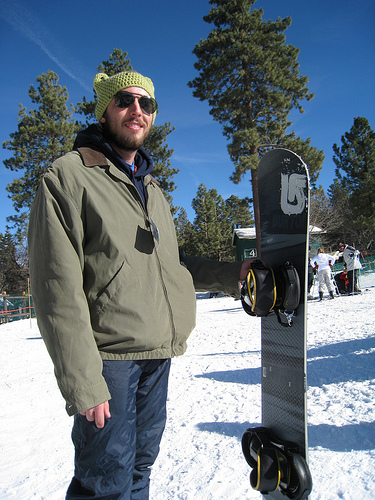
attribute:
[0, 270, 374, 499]
snow — white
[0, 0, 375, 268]
sky — blue, clear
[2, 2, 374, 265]
thin clouds — white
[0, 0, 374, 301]
trees — green, tall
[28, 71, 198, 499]
man — standing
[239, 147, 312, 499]
snowboard — black, standing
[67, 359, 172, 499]
pants — blue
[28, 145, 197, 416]
jacket — green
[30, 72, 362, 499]
people — standing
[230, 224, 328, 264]
building — small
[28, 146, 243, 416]
jacket — green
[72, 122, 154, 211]
sweatshirt — blue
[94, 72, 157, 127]
hat — green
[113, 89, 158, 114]
sunglasses — dark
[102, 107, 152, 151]
beard — dark